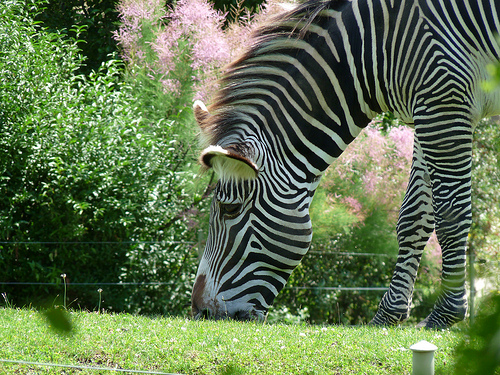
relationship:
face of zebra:
[191, 193, 313, 320] [184, 0, 500, 331]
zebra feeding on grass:
[155, 22, 499, 362] [2, 304, 454, 374]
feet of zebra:
[370, 285, 470, 334] [186, 87, 381, 341]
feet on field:
[370, 285, 470, 334] [2, 304, 498, 374]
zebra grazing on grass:
[184, 0, 500, 331] [2, 295, 493, 371]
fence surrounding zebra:
[3, 273, 495, 334] [152, 7, 488, 349]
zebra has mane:
[184, 0, 500, 331] [172, 0, 329, 203]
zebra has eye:
[184, 0, 500, 331] [220, 202, 244, 215]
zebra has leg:
[184, 0, 500, 331] [360, 125, 438, 326]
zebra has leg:
[184, 0, 500, 331] [411, 83, 475, 331]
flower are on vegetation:
[112, 0, 155, 48] [0, 0, 204, 320]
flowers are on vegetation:
[147, 13, 189, 96] [0, 0, 204, 320]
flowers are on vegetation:
[197, 16, 254, 102] [0, 0, 204, 320]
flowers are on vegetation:
[341, 127, 414, 199] [0, 0, 204, 320]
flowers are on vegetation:
[378, 119, 414, 210] [0, 0, 204, 320]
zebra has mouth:
[184, 0, 500, 331] [222, 306, 259, 324]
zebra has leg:
[184, 0, 500, 331] [415, 112, 480, 334]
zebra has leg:
[184, 0, 500, 331] [365, 140, 430, 325]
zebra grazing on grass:
[184, 0, 500, 331] [10, 313, 393, 373]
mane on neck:
[198, 13, 309, 140] [214, 5, 389, 165]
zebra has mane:
[184, 0, 500, 331] [198, 13, 309, 140]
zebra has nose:
[184, 0, 500, 331] [182, 265, 214, 315]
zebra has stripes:
[184, 0, 500, 331] [189, 2, 496, 319]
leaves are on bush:
[1, 4, 200, 316] [4, 2, 201, 315]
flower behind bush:
[112, 4, 155, 48] [1, 4, 217, 332]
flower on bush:
[112, 0, 155, 48] [4, 2, 201, 315]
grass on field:
[102, 304, 228, 369] [2, 304, 498, 374]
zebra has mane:
[184, 0, 500, 331] [202, 19, 294, 149]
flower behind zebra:
[112, 0, 155, 48] [184, 0, 500, 331]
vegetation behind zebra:
[0, 6, 195, 316] [184, 0, 500, 331]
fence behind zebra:
[0, 234, 500, 333] [184, 0, 500, 331]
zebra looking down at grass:
[184, 0, 500, 331] [8, 303, 498, 373]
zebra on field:
[184, 0, 500, 331] [2, 304, 498, 374]